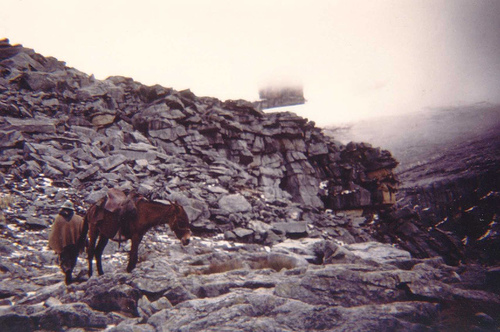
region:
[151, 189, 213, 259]
Horse looking down.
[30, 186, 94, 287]
Girl walking towards camera.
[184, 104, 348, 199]
Rocky wall falling apart.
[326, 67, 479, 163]
Fog in the distance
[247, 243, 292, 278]
Small patch of grass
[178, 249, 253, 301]
Grass growing in between rocks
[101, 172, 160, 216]
Leather to sit on the horse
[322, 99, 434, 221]
Tip of the mountain overlooking rocks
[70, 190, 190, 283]
dark brown horse on ledge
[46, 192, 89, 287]
man in brown cape and hat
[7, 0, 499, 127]
clear white bright sunny sky scene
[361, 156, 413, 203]
brown house built into rocmky cliffs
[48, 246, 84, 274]
man wearing dark green sort pants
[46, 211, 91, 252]
man wearing beige parka over jackets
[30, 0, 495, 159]
there is mist rising off the mountains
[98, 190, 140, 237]
heavy brown leather saddle on horse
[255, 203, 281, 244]
part of a stone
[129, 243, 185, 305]
part of a stand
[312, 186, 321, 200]
part of a rock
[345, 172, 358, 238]
edge of a rock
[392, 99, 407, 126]
part of a cloud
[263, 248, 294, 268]
part of a rock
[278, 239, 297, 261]
side of a rock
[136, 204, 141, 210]
part of a horse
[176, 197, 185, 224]
part of a horse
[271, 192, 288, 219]
edge of a rock